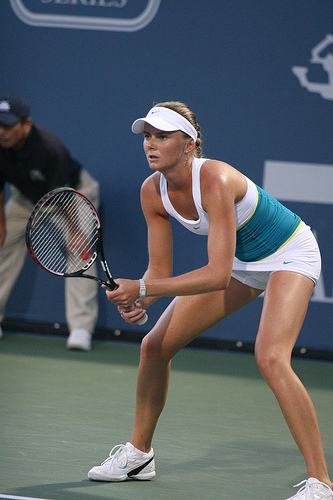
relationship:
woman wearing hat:
[79, 100, 329, 497] [123, 101, 201, 140]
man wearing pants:
[0, 95, 100, 351] [1, 174, 106, 330]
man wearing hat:
[2, 93, 102, 349] [0, 91, 32, 127]